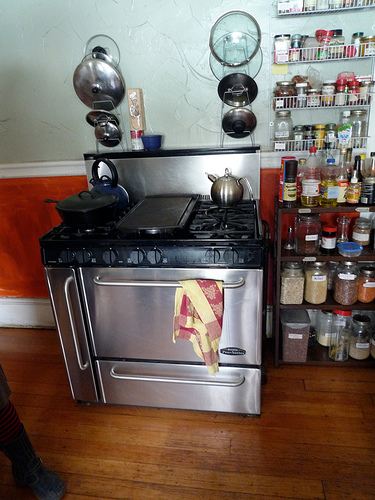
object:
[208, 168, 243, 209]
kettle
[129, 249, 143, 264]
knobs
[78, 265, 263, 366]
oven door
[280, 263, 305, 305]
jars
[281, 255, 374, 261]
shelf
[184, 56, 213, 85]
cracks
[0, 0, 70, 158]
wall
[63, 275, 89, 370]
handle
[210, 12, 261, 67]
lids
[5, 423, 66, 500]
shoe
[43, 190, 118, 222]
pan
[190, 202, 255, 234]
stove